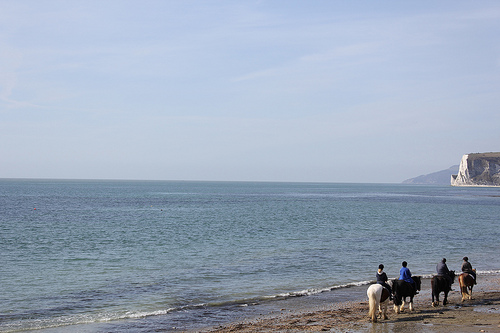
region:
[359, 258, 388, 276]
black riders hat and blonde hair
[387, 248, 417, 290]
person wearing a blue shirt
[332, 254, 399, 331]
person on a white horse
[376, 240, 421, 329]
person on a brown a nd white horse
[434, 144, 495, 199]
a tall cliff over water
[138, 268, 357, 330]
small wave of water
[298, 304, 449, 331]
sand with puddles of water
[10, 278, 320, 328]
white wave on a sandy shore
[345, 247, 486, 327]
four people riding a horse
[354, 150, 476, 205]
mountain next to a cliff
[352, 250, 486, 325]
four people riding a horse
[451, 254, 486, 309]
person riding a brown horse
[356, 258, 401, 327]
person riding a white horse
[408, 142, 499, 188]
mountains on side of ocean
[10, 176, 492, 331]
people riding horses on shore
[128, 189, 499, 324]
people riding horses near the ocean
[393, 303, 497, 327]
shadows reflected on sand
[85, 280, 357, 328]
small waves wet the sand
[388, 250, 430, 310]
person riding a horse wears blue top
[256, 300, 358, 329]
sand has marks of horses feet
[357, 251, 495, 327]
A group riding horseback on the beach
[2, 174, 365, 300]
The ocean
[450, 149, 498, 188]
A giant ledge in the backround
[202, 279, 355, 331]
The coastline with calm waves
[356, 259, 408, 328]
Someone riding a white horse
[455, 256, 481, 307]
Someone riding a brown horse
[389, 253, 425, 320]
Some one in a blue coat riding a black and white horse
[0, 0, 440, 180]
A clear day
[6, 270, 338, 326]
A small wave coming to shore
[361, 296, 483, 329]
Hooves riding on a wet beach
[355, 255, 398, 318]
person riding a horse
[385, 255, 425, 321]
person riding a horse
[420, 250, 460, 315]
person riding a horse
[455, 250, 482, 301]
person riding a horse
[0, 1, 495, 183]
blue sky with clouds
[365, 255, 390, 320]
person and horse near water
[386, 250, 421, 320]
person and horse near water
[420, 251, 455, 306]
person and horse near water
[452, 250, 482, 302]
person and horse near water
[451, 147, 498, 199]
cliff near the water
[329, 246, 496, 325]
The people are on horses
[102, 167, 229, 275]
The water is blue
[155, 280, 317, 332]
The waves are rolling in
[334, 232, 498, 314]
4 horses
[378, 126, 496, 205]
Rocks are in the back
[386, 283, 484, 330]
The sandy beach is brown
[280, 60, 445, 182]
The sky is blue and clear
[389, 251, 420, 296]
The person is wearing blue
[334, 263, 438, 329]
The last horse is white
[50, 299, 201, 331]
The wave is white